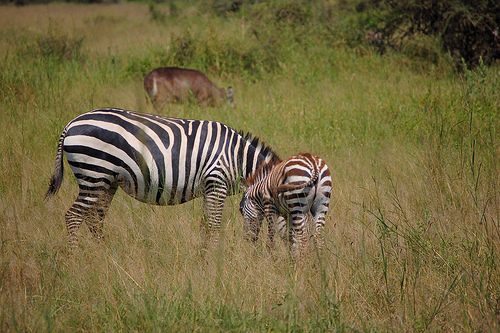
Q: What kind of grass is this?
A: It is dark green grass.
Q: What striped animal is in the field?
A: Zebras.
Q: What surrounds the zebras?
A: Tall grass.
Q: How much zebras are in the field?
A: Two.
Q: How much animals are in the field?
A: Three.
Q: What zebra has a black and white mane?
A: The bigger one.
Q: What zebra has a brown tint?
A: The smallest one.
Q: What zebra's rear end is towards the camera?
A: The smallest one.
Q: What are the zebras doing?
A: Grazing.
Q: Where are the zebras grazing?
A: A grassy field.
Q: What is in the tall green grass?
A: Zebras.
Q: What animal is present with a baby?
A: Zebra.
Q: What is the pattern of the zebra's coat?
A: Striped.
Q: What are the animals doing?
A: Grazing.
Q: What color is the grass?
A: Green.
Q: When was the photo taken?
A: Daytime.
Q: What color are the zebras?
A: Black and white.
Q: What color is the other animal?
A: Brown.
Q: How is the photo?
A: Clear.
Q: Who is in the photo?
A: No one.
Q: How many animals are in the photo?
A: Three.